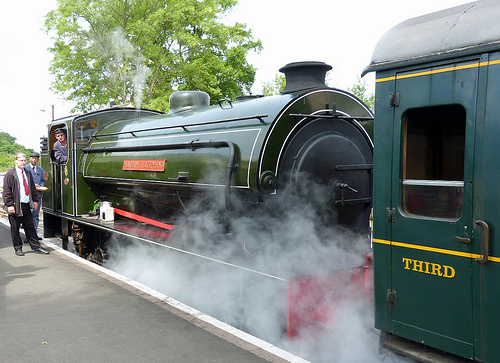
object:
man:
[4, 153, 50, 257]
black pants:
[8, 203, 42, 250]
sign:
[121, 159, 165, 171]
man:
[53, 128, 69, 163]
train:
[40, 0, 500, 363]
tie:
[21, 170, 30, 196]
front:
[256, 90, 376, 230]